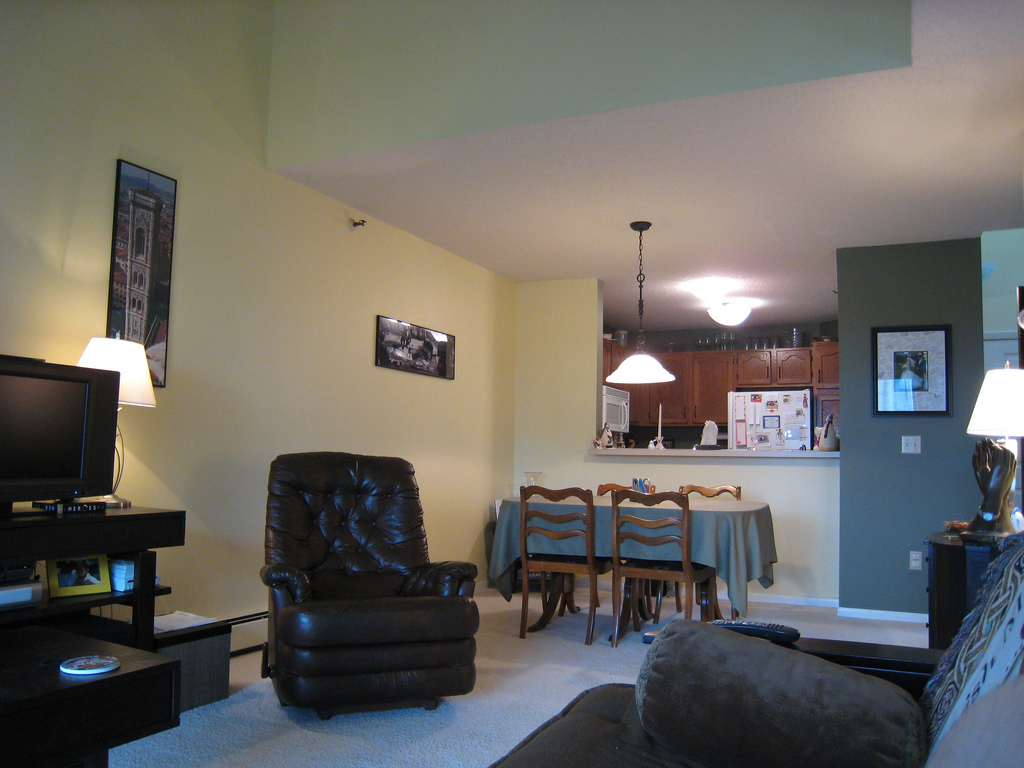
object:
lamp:
[77, 337, 157, 510]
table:
[503, 496, 769, 634]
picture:
[47, 555, 110, 598]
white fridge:
[728, 388, 811, 451]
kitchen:
[588, 323, 842, 460]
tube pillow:
[635, 618, 930, 767]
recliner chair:
[257, 451, 478, 722]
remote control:
[707, 619, 802, 643]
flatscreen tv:
[0, 352, 120, 506]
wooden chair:
[520, 484, 624, 645]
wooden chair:
[611, 490, 715, 648]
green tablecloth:
[488, 497, 776, 618]